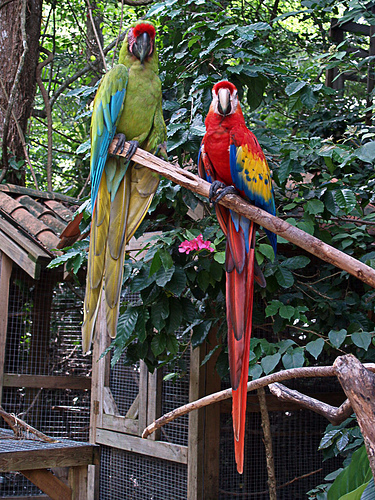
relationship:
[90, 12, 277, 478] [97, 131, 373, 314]
parrots on stick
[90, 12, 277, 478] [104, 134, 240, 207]
parrots have claws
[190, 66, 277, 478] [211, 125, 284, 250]
parrots has wings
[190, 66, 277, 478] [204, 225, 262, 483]
parrots has tail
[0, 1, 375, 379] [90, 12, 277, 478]
trees behind parrots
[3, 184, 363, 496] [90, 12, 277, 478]
cages behind parrots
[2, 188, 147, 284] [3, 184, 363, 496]
roof on cages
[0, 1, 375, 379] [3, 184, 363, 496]
trees behind cages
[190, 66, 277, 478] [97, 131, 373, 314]
parrots on stick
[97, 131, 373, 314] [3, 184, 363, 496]
stick near cages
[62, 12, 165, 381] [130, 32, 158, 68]
parrot has beak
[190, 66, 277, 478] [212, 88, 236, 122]
parrots has beak